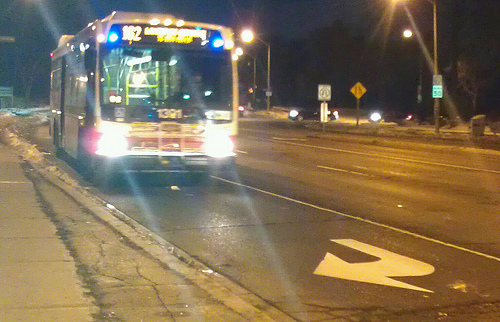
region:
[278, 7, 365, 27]
the sky is black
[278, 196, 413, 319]
the arrow sign on the ground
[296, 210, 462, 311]
the arrow is white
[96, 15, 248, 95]
the bus number is 162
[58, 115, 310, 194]
the lights are turned on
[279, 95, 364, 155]
the car is black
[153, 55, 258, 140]
the bus driver behind the wheel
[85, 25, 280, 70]
the lights are blue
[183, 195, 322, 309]
the street is gray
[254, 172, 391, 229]
the line is white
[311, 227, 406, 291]
white arrow on the road.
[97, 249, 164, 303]
cracks in the sidewalk.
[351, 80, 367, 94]
yellow sign on post.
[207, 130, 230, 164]
headlight on front of bus.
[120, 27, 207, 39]
screen on front of bus.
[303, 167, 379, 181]
white lines painted on the road.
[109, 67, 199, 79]
windshield on front of bus.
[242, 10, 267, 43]
street light on top of pole.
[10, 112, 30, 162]
snow on side of road.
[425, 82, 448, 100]
speed limit sign.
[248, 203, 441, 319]
turn arrow painted on road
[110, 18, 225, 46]
electric sign on bus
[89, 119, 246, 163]
headlights on front of bus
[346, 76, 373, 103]
lane merge road sign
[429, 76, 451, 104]
speed limit sign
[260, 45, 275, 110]
grey metal light pole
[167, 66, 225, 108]
Bus driver steering bus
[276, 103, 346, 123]
black car on road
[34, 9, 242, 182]
A passenger bus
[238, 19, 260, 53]
a large street light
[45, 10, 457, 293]
picture taken at night time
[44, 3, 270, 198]
white bus on street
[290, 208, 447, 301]
white arrow painted on street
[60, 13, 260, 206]
bus with headlights and safety lights on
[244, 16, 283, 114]
tall street lights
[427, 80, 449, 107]
speed limit sign attached to pole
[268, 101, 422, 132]
cars with their headlights on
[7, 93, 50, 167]
pile of white snow on the side of street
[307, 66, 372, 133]
two street signs on the side of the street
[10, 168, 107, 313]
side walk along street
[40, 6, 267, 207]
the bus is #1391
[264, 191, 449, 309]
turn arrow on the street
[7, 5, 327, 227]
this bus has two headlights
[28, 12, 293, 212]
red and white bus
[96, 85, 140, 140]
the bus is handicapped accessible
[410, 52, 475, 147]
speed limit is 50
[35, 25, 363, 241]
this is a night time scene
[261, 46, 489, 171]
the season is winter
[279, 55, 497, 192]
cars are getting off the freeway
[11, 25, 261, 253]
the bus is pulled up to the sidewalk